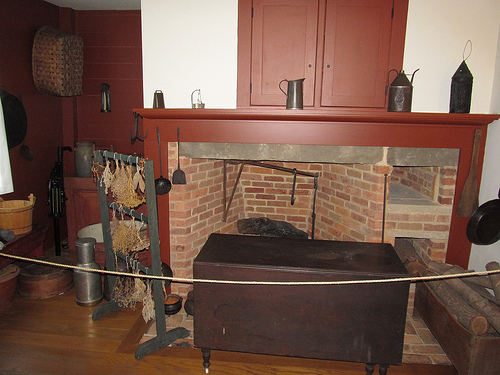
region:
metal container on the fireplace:
[275, 78, 305, 108]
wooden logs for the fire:
[423, 257, 498, 336]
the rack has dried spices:
[91, 150, 188, 356]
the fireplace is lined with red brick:
[167, 145, 451, 304]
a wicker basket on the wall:
[31, 27, 82, 97]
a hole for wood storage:
[386, 167, 438, 212]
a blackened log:
[236, 215, 305, 236]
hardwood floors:
[2, 286, 317, 371]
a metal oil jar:
[383, 65, 418, 110]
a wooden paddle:
[458, 127, 483, 217]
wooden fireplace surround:
[121, 102, 499, 314]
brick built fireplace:
[170, 138, 457, 308]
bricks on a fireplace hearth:
[138, 283, 446, 368]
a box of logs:
[409, 262, 499, 374]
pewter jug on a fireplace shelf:
[272, 70, 313, 121]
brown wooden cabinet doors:
[231, 0, 416, 112]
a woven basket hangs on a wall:
[26, 18, 84, 105]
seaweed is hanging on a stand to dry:
[81, 145, 196, 362]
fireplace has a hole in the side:
[380, 163, 457, 210]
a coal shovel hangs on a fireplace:
[170, 124, 191, 189]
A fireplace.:
[136, 101, 478, 293]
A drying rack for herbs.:
[91, 150, 180, 350]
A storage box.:
[193, 233, 408, 368]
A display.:
[3, 92, 497, 369]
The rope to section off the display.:
[4, 246, 494, 286]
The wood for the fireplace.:
[415, 260, 497, 340]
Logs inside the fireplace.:
[233, 213, 320, 238]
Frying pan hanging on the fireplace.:
[468, 202, 498, 245]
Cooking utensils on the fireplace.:
[153, 129, 188, 194]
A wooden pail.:
[0, 198, 39, 234]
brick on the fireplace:
[138, 145, 461, 361]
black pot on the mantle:
[275, 73, 317, 113]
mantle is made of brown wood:
[131, 90, 493, 313]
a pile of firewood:
[413, 255, 499, 353]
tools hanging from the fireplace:
[152, 120, 193, 205]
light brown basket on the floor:
[0, 190, 41, 238]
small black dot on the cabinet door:
[306, 60, 316, 70]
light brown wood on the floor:
[4, 248, 496, 371]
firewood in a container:
[408, 249, 498, 373]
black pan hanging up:
[466, 180, 498, 247]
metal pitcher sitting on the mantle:
[274, 73, 308, 114]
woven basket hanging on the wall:
[33, 28, 100, 94]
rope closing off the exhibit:
[8, 238, 488, 300]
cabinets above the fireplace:
[241, 5, 428, 115]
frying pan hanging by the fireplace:
[468, 185, 499, 248]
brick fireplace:
[202, 176, 356, 216]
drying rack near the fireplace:
[98, 150, 153, 332]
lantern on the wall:
[96, 73, 112, 120]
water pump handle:
[41, 131, 76, 257]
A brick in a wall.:
[323, 185, 340, 195]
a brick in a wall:
[182, 165, 198, 175]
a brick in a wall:
[198, 162, 213, 172]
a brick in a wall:
[211, 157, 228, 169]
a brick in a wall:
[221, 166, 237, 173]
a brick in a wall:
[188, 171, 205, 182]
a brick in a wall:
[205, 167, 222, 177]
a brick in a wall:
[171, 181, 186, 193]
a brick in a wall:
[164, 192, 191, 201]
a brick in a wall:
[171, 208, 191, 220]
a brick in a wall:
[171, 225, 190, 235]